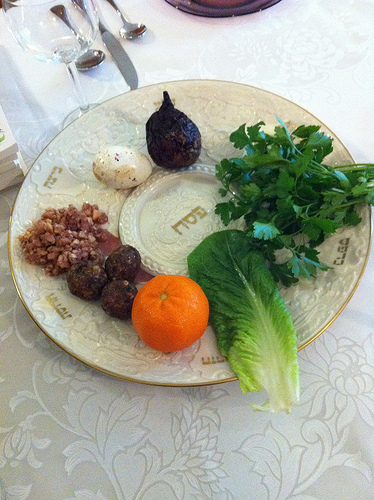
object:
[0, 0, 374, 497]
tablecloth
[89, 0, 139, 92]
knife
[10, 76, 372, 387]
plate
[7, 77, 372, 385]
border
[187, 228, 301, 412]
romaine lettuce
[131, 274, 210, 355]
orange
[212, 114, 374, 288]
parsley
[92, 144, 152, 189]
egg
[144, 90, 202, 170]
fig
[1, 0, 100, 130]
wine glass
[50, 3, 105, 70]
spoon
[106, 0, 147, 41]
spoon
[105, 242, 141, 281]
meatball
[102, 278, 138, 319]
meatball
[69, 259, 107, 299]
meatball